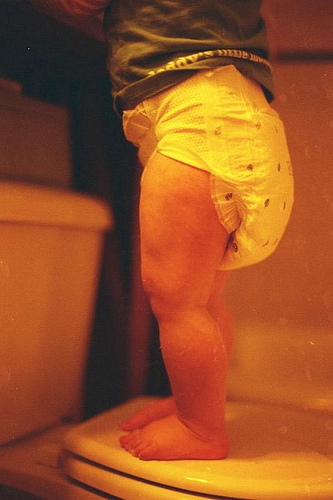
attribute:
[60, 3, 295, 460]
toddler — barefoot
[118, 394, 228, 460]
feet — tiny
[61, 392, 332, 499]
lid — white, porcelin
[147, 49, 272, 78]
writing — white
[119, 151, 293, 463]
baby — white, spotted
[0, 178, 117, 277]
lid — white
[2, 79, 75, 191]
tissue box — blurry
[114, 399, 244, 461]
feet — short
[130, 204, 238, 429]
legs — pink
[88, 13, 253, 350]
child — standing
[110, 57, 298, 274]
diaper — white